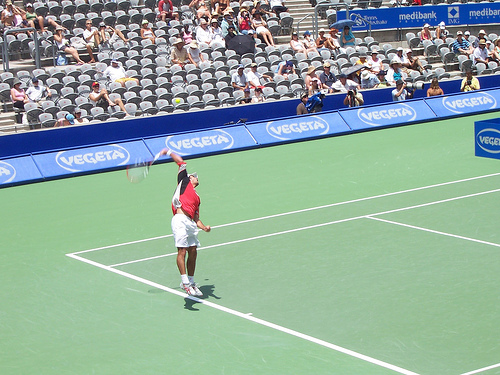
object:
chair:
[172, 92, 190, 101]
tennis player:
[159, 146, 213, 297]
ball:
[172, 97, 183, 105]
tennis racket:
[125, 150, 165, 184]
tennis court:
[0, 111, 498, 373]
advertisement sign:
[246, 113, 348, 146]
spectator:
[86, 81, 131, 117]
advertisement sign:
[337, 7, 497, 28]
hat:
[88, 83, 101, 86]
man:
[341, 84, 363, 108]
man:
[458, 71, 480, 93]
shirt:
[460, 76, 484, 94]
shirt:
[170, 159, 203, 224]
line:
[60, 252, 436, 374]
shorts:
[169, 213, 202, 251]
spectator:
[302, 66, 320, 86]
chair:
[199, 72, 212, 83]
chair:
[57, 97, 74, 111]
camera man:
[388, 79, 423, 100]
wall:
[0, 73, 499, 191]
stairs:
[287, 6, 329, 40]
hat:
[338, 73, 349, 80]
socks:
[179, 273, 190, 290]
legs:
[96, 94, 117, 107]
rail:
[290, 13, 322, 38]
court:
[0, 112, 499, 374]